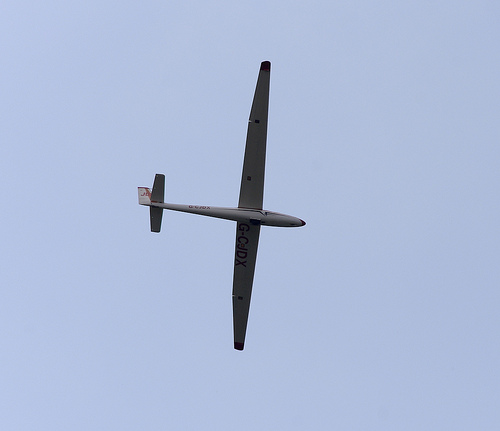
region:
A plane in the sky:
[135, 52, 303, 348]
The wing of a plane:
[228, 221, 260, 350]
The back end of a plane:
[129, 168, 213, 240]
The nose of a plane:
[293, 214, 306, 229]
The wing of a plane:
[238, 54, 273, 206]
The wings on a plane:
[231, 58, 274, 353]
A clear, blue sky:
[7, 8, 497, 429]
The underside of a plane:
[137, 173, 318, 244]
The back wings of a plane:
[146, 172, 168, 232]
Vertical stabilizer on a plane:
[136, 182, 153, 204]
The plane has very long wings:
[227, 59, 274, 353]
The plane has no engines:
[131, 58, 308, 353]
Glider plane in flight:
[133, 57, 310, 354]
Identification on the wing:
[234, 219, 251, 269]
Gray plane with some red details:
[133, 59, 308, 354]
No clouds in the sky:
[1, 0, 498, 430]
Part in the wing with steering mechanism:
[246, 116, 258, 126]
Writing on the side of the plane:
[185, 203, 212, 211]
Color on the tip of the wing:
[233, 339, 245, 350]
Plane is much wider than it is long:
[133, 58, 310, 353]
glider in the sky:
[131, 55, 310, 358]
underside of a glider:
[132, 58, 309, 353]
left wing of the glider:
[227, 219, 260, 352]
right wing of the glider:
[238, 48, 273, 210]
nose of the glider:
[263, 206, 309, 233]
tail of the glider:
[136, 169, 168, 237]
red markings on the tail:
[135, 182, 152, 204]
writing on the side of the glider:
[181, 203, 214, 211]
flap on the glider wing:
[229, 251, 246, 301]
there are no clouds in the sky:
[1, 0, 497, 428]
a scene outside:
[5, 13, 497, 410]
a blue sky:
[5, 8, 497, 426]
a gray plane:
[26, 13, 498, 428]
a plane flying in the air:
[13, 9, 424, 416]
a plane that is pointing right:
[19, 2, 417, 422]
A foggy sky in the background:
[318, 342, 387, 410]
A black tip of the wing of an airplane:
[226, 339, 245, 351]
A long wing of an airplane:
[237, 92, 274, 141]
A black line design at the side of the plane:
[228, 205, 289, 221]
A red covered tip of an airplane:
[297, 216, 310, 228]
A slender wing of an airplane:
[228, 54, 287, 208]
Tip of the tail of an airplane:
[134, 179, 149, 191]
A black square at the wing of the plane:
[240, 169, 255, 185]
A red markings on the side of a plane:
[183, 202, 215, 212]